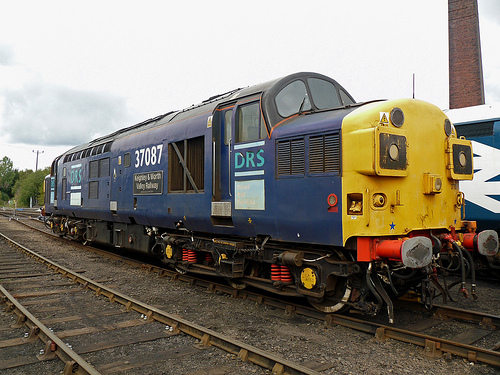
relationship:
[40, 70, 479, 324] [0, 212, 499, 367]
engine car on tracks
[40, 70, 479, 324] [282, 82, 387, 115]
engine car has windows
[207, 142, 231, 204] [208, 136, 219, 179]
handle on train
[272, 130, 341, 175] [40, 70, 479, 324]
vent in engine car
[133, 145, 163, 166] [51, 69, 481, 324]
numbers on train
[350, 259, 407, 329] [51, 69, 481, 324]
cords on train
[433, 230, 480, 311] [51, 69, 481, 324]
cords on train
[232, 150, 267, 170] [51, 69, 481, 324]
sign on train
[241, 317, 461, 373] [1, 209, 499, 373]
rocks on ground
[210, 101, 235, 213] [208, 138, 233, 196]
door with railings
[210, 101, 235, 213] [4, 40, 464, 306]
door on train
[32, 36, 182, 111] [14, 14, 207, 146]
cloud in sky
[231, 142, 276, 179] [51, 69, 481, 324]
letters on train